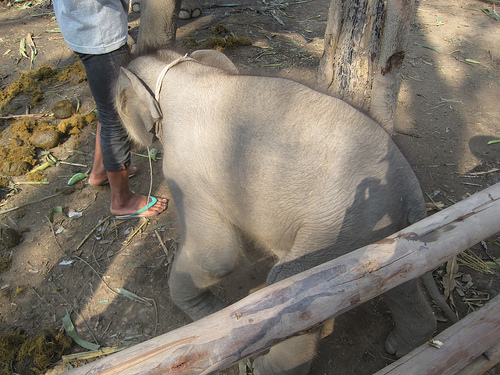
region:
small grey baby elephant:
[88, 47, 467, 351]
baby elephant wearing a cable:
[140, 43, 194, 111]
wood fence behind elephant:
[177, 210, 499, 370]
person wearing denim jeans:
[70, 43, 167, 230]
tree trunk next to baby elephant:
[323, 0, 415, 262]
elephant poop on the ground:
[16, 58, 84, 178]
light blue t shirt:
[58, 2, 135, 49]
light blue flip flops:
[86, 171, 173, 249]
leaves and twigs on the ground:
[46, 226, 156, 326]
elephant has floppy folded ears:
[113, 60, 175, 168]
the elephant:
[67, 51, 469, 362]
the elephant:
[80, 81, 355, 295]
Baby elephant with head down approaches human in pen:
[107, 35, 409, 370]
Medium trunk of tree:
[327, 2, 407, 140]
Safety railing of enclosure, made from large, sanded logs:
[33, 200, 498, 372]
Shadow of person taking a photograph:
[286, 99, 446, 260]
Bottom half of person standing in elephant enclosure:
[40, 1, 180, 230]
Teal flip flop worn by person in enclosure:
[106, 183, 169, 221]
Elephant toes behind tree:
[118, 1, 214, 25]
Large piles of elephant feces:
[0, 60, 86, 371]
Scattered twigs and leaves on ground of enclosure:
[41, 209, 166, 331]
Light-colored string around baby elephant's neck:
[143, 52, 199, 146]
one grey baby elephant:
[113, 43, 460, 373]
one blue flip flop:
[108, 186, 172, 223]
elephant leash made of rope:
[140, 51, 199, 146]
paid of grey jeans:
[63, 41, 146, 176]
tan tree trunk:
[313, 0, 421, 133]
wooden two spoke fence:
[25, 179, 496, 367]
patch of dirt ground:
[34, 252, 127, 334]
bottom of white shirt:
[50, 1, 133, 53]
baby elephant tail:
[405, 201, 470, 330]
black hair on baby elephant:
[137, 47, 179, 68]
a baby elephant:
[111, 33, 429, 361]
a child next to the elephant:
[45, 0, 180, 220]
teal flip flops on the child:
[80, 157, 160, 230]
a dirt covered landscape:
[0, 14, 486, 361]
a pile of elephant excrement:
[0, 67, 86, 197]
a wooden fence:
[76, 186, 495, 371]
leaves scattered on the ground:
[2, 0, 496, 328]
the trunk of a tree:
[274, 4, 454, 226]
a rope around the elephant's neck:
[131, 47, 205, 168]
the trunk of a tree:
[116, 0, 211, 83]